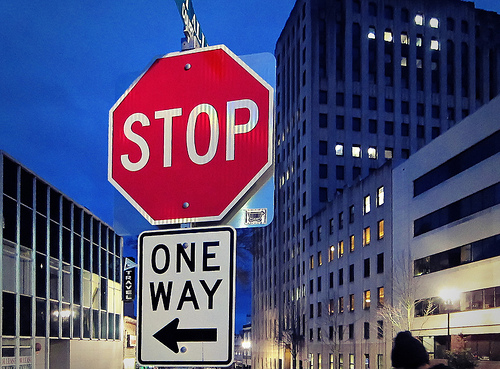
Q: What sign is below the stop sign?
A: One way.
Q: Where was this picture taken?
A: A city.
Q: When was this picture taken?
A: Nighttime.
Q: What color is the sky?
A: Blue.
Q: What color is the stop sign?
A: Red and white.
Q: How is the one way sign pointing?
A: To the left.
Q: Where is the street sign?
A: Above the stop sign.